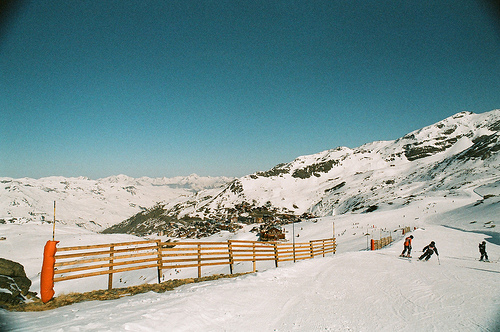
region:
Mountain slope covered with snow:
[0, 110, 497, 330]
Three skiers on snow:
[401, 235, 488, 261]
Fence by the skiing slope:
[41, 200, 423, 302]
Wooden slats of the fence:
[55, 228, 412, 280]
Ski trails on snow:
[395, 251, 499, 325]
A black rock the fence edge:
[0, 257, 39, 307]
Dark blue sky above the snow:
[1, 1, 498, 177]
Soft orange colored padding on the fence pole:
[40, 240, 60, 303]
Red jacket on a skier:
[405, 236, 411, 243]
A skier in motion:
[419, 239, 440, 261]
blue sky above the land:
[123, 43, 209, 96]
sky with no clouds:
[185, 35, 306, 90]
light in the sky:
[45, 125, 150, 170]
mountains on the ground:
[205, 122, 455, 228]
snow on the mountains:
[231, 140, 388, 201]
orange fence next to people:
[30, 220, 351, 297]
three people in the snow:
[380, 215, 495, 286]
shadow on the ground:
[461, 256, 491, 276]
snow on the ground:
[385, 263, 456, 303]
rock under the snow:
[184, 203, 221, 235]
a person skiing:
[396, 232, 418, 260]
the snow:
[249, 280, 394, 323]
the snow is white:
[248, 271, 345, 324]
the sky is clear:
[121, 33, 338, 140]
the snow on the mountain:
[57, 187, 124, 212]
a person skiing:
[417, 233, 444, 265]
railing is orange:
[203, 242, 248, 263]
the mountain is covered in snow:
[351, 142, 425, 197]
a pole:
[46, 202, 68, 239]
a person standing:
[473, 235, 490, 262]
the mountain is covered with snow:
[185, 132, 437, 230]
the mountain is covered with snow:
[120, 168, 369, 254]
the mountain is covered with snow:
[305, 103, 483, 200]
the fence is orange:
[26, 232, 386, 300]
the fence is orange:
[19, 208, 411, 280]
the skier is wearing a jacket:
[402, 235, 412, 245]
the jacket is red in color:
[404, 235, 411, 245]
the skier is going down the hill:
[418, 241, 438, 258]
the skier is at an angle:
[418, 242, 439, 259]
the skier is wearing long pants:
[401, 245, 412, 254]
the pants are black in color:
[403, 244, 412, 254]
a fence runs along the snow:
[38, 232, 341, 302]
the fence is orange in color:
[43, 232, 338, 299]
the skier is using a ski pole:
[437, 256, 442, 264]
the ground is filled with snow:
[1, 215, 498, 330]